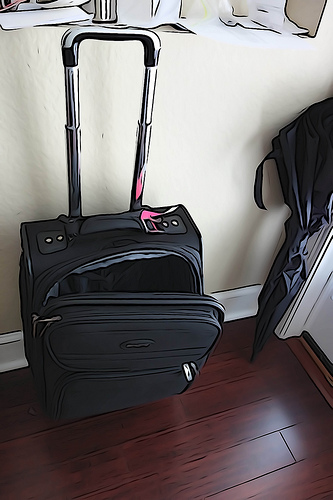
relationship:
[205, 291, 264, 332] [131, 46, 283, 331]
floor board on wall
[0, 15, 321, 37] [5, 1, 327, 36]
edge of painting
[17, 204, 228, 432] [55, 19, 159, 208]
bag has handle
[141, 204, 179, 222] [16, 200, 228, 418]
label on bag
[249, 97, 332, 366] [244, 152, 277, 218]
black umbrella hanging down strap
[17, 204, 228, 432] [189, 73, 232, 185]
bag propped against wall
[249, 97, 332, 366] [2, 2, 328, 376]
black umbrella against wall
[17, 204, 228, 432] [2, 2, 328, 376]
bag against wall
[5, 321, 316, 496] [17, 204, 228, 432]
floor under bag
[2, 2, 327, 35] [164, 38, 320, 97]
picture on wall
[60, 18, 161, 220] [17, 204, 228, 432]
handle on bag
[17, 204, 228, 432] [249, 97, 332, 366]
bag beside black umbrella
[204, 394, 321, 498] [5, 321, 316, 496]
light on floor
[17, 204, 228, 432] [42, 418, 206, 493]
bag casting shadow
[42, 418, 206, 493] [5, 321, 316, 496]
shadow on floor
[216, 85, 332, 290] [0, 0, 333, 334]
shadow on wall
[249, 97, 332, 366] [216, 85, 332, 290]
black umbrella casting shadow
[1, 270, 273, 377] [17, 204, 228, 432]
baseboards behind bag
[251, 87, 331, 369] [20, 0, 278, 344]
black umbrella standing against wall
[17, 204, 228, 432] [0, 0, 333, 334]
bag against wall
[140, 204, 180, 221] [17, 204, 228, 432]
label on bag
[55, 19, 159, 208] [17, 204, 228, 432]
handle on bag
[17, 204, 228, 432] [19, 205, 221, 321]
bag has top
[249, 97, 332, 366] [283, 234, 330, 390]
black umbrella standing by door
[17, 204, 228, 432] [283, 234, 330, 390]
bag standing by door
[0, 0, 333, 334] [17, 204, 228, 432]
wall behind bag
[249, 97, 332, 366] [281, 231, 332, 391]
black umbrella beside door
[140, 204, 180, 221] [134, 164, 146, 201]
label has reflection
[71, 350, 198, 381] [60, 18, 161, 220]
black zip has handle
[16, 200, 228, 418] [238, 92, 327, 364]
bag next to umbrella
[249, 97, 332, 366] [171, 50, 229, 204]
black umbrella propped against wall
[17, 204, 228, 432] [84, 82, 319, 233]
bag against wall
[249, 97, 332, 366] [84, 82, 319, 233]
black umbrella against wall